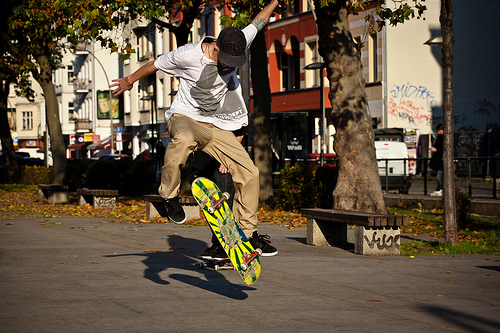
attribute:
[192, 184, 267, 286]
skateboard — yellow, green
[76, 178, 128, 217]
bench — gray, brown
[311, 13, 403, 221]
tree — tall, brown, green, branchless, narrow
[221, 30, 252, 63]
cap — black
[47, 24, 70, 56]
leaves — dry, green, brown, yellow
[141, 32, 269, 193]
man — jumping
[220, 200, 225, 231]
lines — black, green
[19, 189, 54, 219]
leaves — brown, yellow, orange, gold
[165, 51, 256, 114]
shirt — white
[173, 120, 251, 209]
pants — tan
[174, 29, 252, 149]
skateboarder — jumping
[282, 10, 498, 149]
building — red, white, large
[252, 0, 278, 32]
arm — outstretched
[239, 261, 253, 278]
wheel — white, silver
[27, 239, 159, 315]
area — gray, paved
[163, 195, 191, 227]
sneaker — black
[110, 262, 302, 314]
cement — brown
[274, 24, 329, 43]
ledge — orange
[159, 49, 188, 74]
sleeve — short